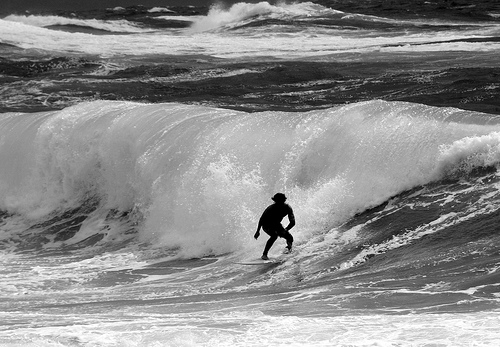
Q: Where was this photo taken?
A: At the beach.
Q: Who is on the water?
A: Surfer.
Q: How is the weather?
A: Good.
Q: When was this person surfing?
A: Daytime.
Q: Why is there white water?
A: Because of agitation.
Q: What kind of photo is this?
A: Black and white.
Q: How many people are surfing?
A: 1.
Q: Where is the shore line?
A: To the lower left.